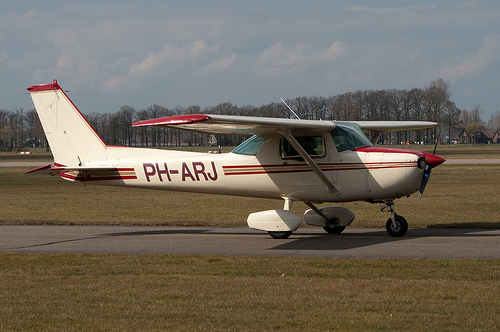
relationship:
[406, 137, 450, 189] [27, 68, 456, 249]
propeller on aiplane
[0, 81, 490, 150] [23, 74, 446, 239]
trees are behind airplane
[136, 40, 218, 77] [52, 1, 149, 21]
clouds in sky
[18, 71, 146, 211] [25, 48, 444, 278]
tail of plane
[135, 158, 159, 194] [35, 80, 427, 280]
letter on plane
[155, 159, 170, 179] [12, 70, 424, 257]
letter on plane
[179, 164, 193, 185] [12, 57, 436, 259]
letter on plane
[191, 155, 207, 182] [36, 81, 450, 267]
letter on plane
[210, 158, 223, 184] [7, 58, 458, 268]
letter on plane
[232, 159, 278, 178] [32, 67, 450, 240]
stripe on plane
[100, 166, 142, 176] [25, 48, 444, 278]
stripe on plane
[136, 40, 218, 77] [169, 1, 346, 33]
clouds in sky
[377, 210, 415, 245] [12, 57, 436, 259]
wheel of plane